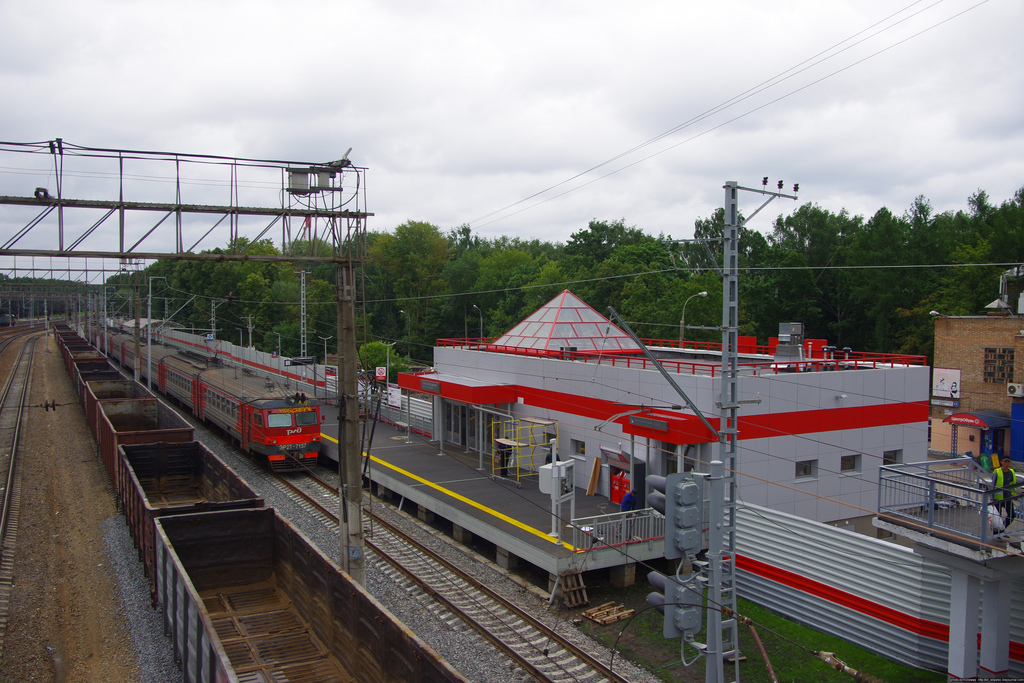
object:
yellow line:
[319, 430, 584, 554]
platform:
[309, 397, 677, 555]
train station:
[313, 284, 931, 544]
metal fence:
[726, 494, 1024, 677]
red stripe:
[717, 542, 1018, 663]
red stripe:
[398, 370, 933, 444]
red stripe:
[160, 335, 333, 391]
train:
[79, 311, 325, 476]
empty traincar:
[151, 502, 477, 679]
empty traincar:
[115, 439, 267, 573]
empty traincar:
[88, 390, 198, 472]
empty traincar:
[77, 371, 157, 432]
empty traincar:
[64, 337, 111, 376]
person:
[985, 457, 1021, 541]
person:
[615, 490, 639, 539]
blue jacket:
[621, 493, 637, 512]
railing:
[876, 455, 1021, 553]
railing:
[573, 509, 667, 553]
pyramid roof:
[498, 289, 640, 358]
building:
[391, 281, 936, 551]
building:
[925, 290, 1022, 461]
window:
[793, 457, 821, 483]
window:
[839, 452, 862, 474]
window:
[884, 448, 904, 472]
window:
[567, 438, 587, 462]